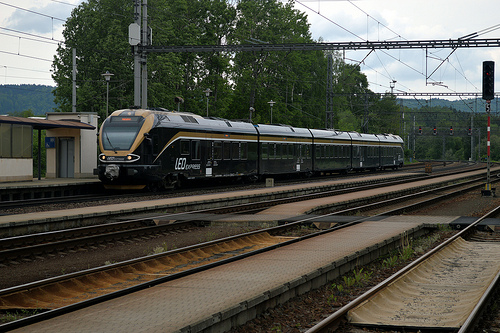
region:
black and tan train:
[103, 110, 406, 182]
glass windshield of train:
[104, 119, 139, 146]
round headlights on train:
[101, 155, 132, 162]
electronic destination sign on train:
[113, 115, 137, 122]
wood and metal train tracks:
[311, 208, 498, 327]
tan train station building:
[4, 114, 94, 181]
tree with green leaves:
[58, 2, 240, 123]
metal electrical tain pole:
[143, 38, 499, 49]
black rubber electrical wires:
[1, 4, 86, 71]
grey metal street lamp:
[103, 70, 110, 116]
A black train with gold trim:
[94, 98, 404, 184]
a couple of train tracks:
[4, 146, 494, 323]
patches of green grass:
[325, 240, 418, 305]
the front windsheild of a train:
[100, 119, 140, 153]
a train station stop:
[1, 112, 97, 194]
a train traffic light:
[477, 58, 497, 184]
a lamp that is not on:
[99, 66, 113, 122]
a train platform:
[0, 118, 103, 198]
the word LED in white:
[167, 154, 189, 174]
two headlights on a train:
[96, 152, 137, 167]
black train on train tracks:
[94, 96, 411, 185]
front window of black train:
[99, 129, 139, 161]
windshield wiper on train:
[101, 132, 121, 155]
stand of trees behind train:
[55, 5, 464, 142]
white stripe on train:
[153, 132, 400, 162]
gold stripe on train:
[160, 123, 409, 148]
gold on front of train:
[90, 105, 157, 164]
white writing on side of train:
[167, 148, 189, 175]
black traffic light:
[480, 61, 494, 103]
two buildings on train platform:
[3, 103, 107, 185]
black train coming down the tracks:
[87, 100, 412, 195]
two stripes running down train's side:
[154, 123, 406, 168]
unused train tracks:
[10, 166, 497, 328]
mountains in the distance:
[391, 90, 498, 124]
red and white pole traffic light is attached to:
[478, 105, 498, 187]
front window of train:
[95, 121, 142, 159]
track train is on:
[5, 150, 468, 199]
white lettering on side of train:
[169, 153, 192, 169]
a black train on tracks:
[91, 101, 437, 187]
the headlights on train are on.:
[98, 150, 145, 167]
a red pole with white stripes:
[479, 108, 495, 173]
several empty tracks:
[28, 151, 495, 331]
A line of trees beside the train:
[64, 0, 493, 155]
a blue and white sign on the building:
[38, 129, 60, 149]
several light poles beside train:
[88, 60, 289, 147]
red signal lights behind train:
[402, 113, 486, 145]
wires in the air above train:
[8, 0, 477, 102]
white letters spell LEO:
[168, 150, 195, 180]